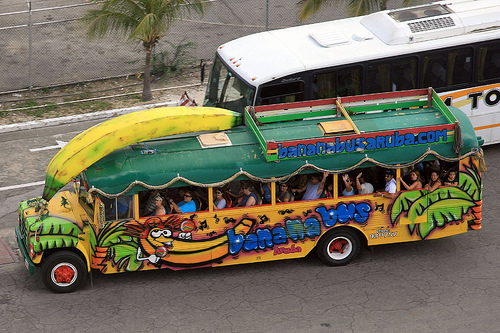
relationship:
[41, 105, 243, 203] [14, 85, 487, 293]
banana on bus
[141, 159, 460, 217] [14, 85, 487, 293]
people on bus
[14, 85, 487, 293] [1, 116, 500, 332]
bus on road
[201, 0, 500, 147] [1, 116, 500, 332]
bus on road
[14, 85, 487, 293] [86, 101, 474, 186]
bus with roof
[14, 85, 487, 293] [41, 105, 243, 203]
bus with banana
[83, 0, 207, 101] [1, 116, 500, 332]
palm tree beside road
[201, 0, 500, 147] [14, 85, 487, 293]
bus next to bus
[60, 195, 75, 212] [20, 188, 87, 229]
lizard on hood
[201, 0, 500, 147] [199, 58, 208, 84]
bus with mirror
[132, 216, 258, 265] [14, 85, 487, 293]
banana in bus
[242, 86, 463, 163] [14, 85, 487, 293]
cargo hold on bus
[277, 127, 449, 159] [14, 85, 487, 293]
website on bus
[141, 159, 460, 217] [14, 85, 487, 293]
people riding bus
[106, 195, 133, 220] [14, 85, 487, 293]
driver for bus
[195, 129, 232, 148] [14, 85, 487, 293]
hatch on top of bus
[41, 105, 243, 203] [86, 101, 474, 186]
banana on roof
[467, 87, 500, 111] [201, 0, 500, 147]
letters on bus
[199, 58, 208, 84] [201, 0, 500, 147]
mirror on bus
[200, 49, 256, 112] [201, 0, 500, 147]
windshield on bus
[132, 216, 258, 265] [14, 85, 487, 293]
banana painted on bus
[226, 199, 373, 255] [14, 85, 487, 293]
letters on bus